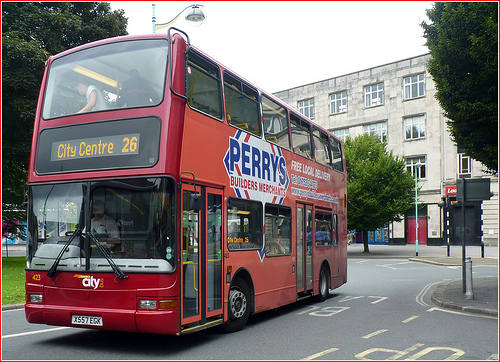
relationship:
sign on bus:
[53, 139, 145, 162] [40, 54, 350, 324]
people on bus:
[71, 75, 146, 111] [40, 54, 350, 324]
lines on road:
[364, 321, 387, 343] [339, 297, 488, 356]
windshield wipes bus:
[29, 190, 180, 258] [40, 54, 350, 324]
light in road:
[187, 5, 209, 24] [339, 297, 488, 356]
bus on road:
[40, 54, 350, 324] [339, 297, 488, 356]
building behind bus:
[341, 61, 429, 136] [40, 54, 350, 324]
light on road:
[187, 5, 209, 24] [339, 297, 488, 356]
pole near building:
[457, 179, 473, 297] [341, 61, 429, 136]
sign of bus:
[53, 139, 145, 162] [40, 54, 350, 324]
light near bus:
[187, 5, 209, 24] [40, 54, 350, 324]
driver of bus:
[81, 197, 123, 245] [40, 54, 350, 324]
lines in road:
[364, 321, 387, 343] [339, 297, 488, 356]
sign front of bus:
[53, 139, 145, 162] [40, 54, 350, 324]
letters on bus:
[229, 137, 287, 185] [40, 54, 350, 324]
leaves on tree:
[436, 41, 459, 63] [422, 8, 493, 122]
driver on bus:
[81, 197, 123, 245] [40, 54, 350, 324]